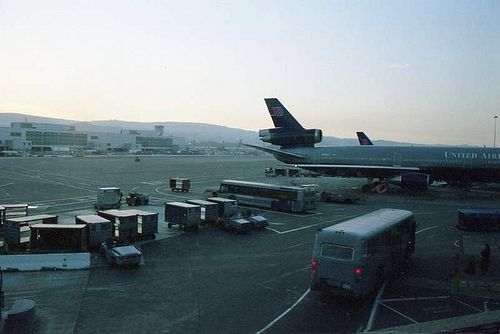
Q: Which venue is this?
A: This is a runway.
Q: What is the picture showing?
A: It is showing a runway.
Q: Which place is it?
A: It is a runway.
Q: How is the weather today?
A: It is overcast.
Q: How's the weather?
A: It is overcast.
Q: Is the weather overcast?
A: Yes, it is overcast.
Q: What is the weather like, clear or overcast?
A: It is overcast.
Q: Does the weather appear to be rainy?
A: No, it is overcast.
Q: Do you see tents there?
A: No, there are no tents.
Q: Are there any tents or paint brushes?
A: No, there are no tents or paint brushes.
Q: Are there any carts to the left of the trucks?
A: Yes, there is a cart to the left of the trucks.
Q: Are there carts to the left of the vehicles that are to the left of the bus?
A: Yes, there is a cart to the left of the trucks.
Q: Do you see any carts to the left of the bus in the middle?
A: Yes, there is a cart to the left of the bus.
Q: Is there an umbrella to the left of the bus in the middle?
A: No, there is a cart to the left of the bus.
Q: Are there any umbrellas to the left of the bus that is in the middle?
A: No, there is a cart to the left of the bus.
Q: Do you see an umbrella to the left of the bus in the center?
A: No, there is a cart to the left of the bus.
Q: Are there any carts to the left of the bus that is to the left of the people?
A: Yes, there is a cart to the left of the bus.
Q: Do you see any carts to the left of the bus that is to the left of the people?
A: Yes, there is a cart to the left of the bus.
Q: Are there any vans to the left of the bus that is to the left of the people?
A: No, there is a cart to the left of the bus.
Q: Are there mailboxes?
A: No, there are no mailboxes.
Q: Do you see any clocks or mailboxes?
A: No, there are no mailboxes or clocks.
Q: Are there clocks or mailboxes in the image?
A: No, there are no mailboxes or clocks.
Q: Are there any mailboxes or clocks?
A: No, there are no mailboxes or clocks.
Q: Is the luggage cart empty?
A: Yes, the luggage cart is empty.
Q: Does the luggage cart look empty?
A: Yes, the luggage cart is empty.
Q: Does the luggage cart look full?
A: No, the luggage cart is empty.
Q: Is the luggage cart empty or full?
A: The luggage cart is empty.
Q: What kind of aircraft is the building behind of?
A: The building is behind the airplane.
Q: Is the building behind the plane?
A: Yes, the building is behind the plane.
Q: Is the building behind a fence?
A: No, the building is behind the plane.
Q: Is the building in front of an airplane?
A: No, the building is behind an airplane.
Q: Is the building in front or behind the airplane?
A: The building is behind the airplane.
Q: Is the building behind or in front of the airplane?
A: The building is behind the airplane.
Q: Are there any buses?
A: Yes, there is a bus.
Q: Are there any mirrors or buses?
A: Yes, there is a bus.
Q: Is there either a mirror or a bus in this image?
A: Yes, there is a bus.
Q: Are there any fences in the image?
A: No, there are no fences.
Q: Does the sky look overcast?
A: Yes, the sky is overcast.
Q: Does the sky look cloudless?
A: No, the sky is overcast.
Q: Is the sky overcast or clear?
A: The sky is overcast.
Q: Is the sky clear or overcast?
A: The sky is overcast.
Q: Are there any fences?
A: No, there are no fences.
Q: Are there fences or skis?
A: No, there are no fences or skis.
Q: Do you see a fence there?
A: No, there are no fences.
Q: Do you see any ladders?
A: No, there are no ladders.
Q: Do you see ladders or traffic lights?
A: No, there are no ladders or traffic lights.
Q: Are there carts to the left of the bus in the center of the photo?
A: Yes, there is a cart to the left of the bus.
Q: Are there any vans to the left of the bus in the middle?
A: No, there is a cart to the left of the bus.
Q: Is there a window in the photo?
A: Yes, there is a window.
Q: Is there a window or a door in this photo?
A: Yes, there is a window.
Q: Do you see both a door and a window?
A: No, there is a window but no doors.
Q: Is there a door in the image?
A: No, there are no doors.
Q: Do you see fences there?
A: No, there are no fences.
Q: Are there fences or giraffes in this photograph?
A: No, there are no fences or giraffes.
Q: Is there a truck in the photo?
A: Yes, there are trucks.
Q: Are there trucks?
A: Yes, there are trucks.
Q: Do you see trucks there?
A: Yes, there are trucks.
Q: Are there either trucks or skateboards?
A: Yes, there are trucks.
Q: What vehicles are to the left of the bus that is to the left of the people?
A: The vehicles are trucks.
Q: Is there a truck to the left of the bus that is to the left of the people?
A: Yes, there are trucks to the left of the bus.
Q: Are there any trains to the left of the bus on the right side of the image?
A: No, there are trucks to the left of the bus.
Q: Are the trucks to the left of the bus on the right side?
A: Yes, the trucks are to the left of the bus.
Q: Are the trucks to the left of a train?
A: No, the trucks are to the left of the bus.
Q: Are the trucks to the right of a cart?
A: Yes, the trucks are to the right of a cart.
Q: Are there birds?
A: No, there are no birds.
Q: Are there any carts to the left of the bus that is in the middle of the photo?
A: Yes, there is a cart to the left of the bus.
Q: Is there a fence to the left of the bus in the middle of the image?
A: No, there is a cart to the left of the bus.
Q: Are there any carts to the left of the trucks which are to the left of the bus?
A: Yes, there is a cart to the left of the trucks.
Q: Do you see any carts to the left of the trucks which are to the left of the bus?
A: Yes, there is a cart to the left of the trucks.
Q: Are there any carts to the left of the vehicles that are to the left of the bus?
A: Yes, there is a cart to the left of the trucks.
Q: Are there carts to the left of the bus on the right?
A: Yes, there is a cart to the left of the bus.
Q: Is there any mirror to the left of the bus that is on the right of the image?
A: No, there is a cart to the left of the bus.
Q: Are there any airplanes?
A: Yes, there is an airplane.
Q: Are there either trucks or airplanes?
A: Yes, there is an airplane.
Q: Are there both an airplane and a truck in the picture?
A: Yes, there are both an airplane and a truck.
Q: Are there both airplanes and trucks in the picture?
A: Yes, there are both an airplane and a truck.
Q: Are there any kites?
A: No, there are no kites.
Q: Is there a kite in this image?
A: No, there are no kites.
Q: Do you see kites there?
A: No, there are no kites.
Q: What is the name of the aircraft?
A: The aircraft is an airplane.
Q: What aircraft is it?
A: The aircraft is an airplane.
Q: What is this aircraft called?
A: This is an airplane.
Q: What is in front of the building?
A: The airplane is in front of the building.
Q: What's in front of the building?
A: The airplane is in front of the building.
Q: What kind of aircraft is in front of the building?
A: The aircraft is an airplane.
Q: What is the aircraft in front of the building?
A: The aircraft is an airplane.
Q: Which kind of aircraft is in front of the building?
A: The aircraft is an airplane.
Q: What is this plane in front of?
A: The plane is in front of the building.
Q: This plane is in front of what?
A: The plane is in front of the building.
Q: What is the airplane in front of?
A: The plane is in front of the building.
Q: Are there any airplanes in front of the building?
A: Yes, there is an airplane in front of the building.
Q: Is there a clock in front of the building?
A: No, there is an airplane in front of the building.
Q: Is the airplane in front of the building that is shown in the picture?
A: Yes, the airplane is in front of the building.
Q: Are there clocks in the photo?
A: No, there are no clocks.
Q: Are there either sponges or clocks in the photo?
A: No, there are no clocks or sponges.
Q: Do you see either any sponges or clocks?
A: No, there are no clocks or sponges.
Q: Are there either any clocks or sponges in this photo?
A: No, there are no clocks or sponges.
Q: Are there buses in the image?
A: Yes, there is a bus.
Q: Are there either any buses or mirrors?
A: Yes, there is a bus.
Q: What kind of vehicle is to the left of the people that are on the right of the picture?
A: The vehicle is a bus.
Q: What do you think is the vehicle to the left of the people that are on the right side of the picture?
A: The vehicle is a bus.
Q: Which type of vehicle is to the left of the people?
A: The vehicle is a bus.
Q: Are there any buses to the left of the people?
A: Yes, there is a bus to the left of the people.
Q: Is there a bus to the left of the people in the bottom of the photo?
A: Yes, there is a bus to the left of the people.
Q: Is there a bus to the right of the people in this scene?
A: No, the bus is to the left of the people.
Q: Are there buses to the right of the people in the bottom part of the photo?
A: No, the bus is to the left of the people.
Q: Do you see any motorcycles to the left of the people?
A: No, there is a bus to the left of the people.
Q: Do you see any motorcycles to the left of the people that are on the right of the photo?
A: No, there is a bus to the left of the people.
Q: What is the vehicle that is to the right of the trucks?
A: The vehicle is a bus.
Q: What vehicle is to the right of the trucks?
A: The vehicle is a bus.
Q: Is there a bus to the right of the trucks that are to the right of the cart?
A: Yes, there is a bus to the right of the trucks.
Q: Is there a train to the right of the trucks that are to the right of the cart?
A: No, there is a bus to the right of the trucks.